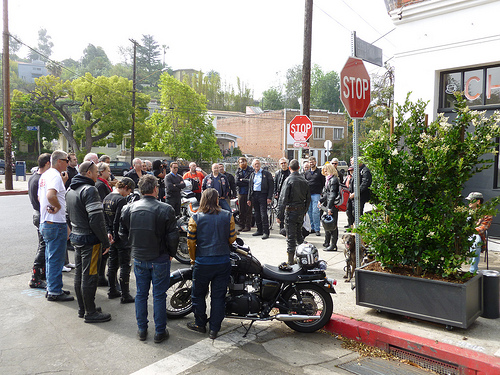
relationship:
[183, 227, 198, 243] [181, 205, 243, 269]
blue strips on sleeve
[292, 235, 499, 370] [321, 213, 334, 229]
sidewalk holds helmet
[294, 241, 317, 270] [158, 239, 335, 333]
helmet on motorcycle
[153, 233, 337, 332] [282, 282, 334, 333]
motorcycle has wheel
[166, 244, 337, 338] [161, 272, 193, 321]
motorcycle has wheel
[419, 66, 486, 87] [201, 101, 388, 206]
window on building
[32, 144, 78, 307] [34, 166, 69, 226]
man wears shirt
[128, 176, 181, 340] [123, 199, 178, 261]
man wears jacket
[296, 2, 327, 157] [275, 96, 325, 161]
post on sign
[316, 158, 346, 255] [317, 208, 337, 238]
woman holds helmet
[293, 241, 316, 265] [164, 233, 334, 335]
helmet on motorcycle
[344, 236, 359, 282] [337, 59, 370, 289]
dog on stop sign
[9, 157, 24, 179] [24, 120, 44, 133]
mailbox next to sign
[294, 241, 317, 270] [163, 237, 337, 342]
helmet on motorcycle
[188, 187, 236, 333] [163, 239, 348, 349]
woman standing next to motorcycle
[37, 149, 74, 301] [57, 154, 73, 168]
man has sunglasses